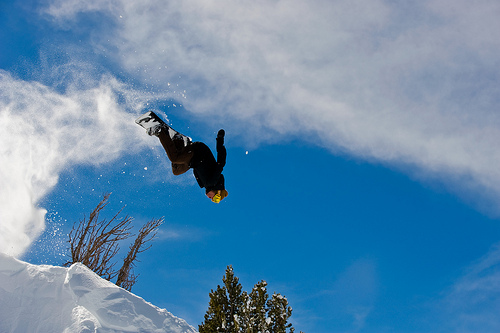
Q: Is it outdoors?
A: Yes, it is outdoors.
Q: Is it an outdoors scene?
A: Yes, it is outdoors.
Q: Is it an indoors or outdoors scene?
A: It is outdoors.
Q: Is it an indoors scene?
A: No, it is outdoors.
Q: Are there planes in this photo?
A: No, there are no planes.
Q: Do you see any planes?
A: No, there are no planes.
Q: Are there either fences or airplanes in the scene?
A: No, there are no airplanes or fences.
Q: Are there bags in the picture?
A: No, there are no bags.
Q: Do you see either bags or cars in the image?
A: No, there are no bags or cars.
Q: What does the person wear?
A: The person wears trousers.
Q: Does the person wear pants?
A: Yes, the person wears pants.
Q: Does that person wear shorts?
A: No, the person wears pants.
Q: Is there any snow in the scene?
A: Yes, there is snow.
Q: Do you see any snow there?
A: Yes, there is snow.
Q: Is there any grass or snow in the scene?
A: Yes, there is snow.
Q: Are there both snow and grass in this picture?
A: No, there is snow but no grass.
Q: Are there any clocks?
A: No, there are no clocks.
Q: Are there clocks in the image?
A: No, there are no clocks.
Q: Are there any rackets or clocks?
A: No, there are no clocks or rackets.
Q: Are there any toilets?
A: No, there are no toilets.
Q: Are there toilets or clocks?
A: No, there are no toilets or clocks.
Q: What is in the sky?
A: The clouds are in the sky.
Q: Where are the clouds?
A: The clouds are in the sky.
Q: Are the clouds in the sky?
A: Yes, the clouds are in the sky.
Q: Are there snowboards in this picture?
A: Yes, there is a snowboard.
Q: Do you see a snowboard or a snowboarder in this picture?
A: Yes, there is a snowboard.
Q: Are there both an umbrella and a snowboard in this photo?
A: No, there is a snowboard but no umbrellas.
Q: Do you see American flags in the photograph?
A: No, there are no American flags.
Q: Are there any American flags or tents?
A: No, there are no American flags or tents.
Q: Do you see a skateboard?
A: No, there are no skateboards.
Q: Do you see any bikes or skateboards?
A: No, there are no skateboards or bikes.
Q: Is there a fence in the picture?
A: No, there are no fences.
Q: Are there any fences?
A: No, there are no fences.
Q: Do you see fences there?
A: No, there are no fences.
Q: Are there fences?
A: No, there are no fences.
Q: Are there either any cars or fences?
A: No, there are no fences or cars.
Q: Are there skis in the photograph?
A: No, there are no skis.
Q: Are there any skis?
A: No, there are no skis.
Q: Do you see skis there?
A: No, there are no skis.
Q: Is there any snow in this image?
A: Yes, there is snow.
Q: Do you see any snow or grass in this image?
A: Yes, there is snow.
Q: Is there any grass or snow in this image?
A: Yes, there is snow.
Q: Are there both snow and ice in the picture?
A: No, there is snow but no ice.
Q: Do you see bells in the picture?
A: No, there are no bells.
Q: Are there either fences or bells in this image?
A: No, there are no bells or fences.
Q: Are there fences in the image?
A: No, there are no fences.